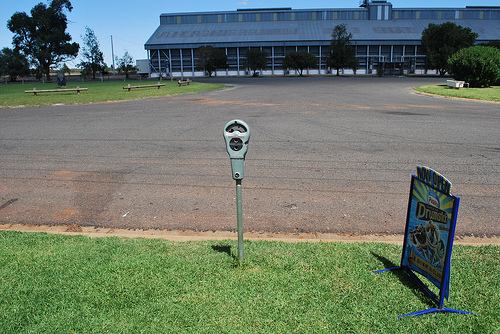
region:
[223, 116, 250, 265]
a lone parking meter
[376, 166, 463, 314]
a sign advertising icecream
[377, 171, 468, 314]
colorful sign in a blue frame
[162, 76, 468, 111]
large empty parking lot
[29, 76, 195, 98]
log railing on the grass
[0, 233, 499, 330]
grass is think and green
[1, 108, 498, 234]
a paved roadway passes the parking meter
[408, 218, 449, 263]
three ice cream cones against a blue background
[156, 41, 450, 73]
front of the building is screened in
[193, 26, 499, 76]
bushes and trees grow against the front of the building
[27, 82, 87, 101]
Small wooden bench in the grass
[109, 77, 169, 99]
Small wooden bench in the grass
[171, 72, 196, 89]
Small wooden bench in the grass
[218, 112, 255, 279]
Metal parking meter in the grass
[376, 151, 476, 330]
Colorful sign in the grass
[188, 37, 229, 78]
Large tree by a building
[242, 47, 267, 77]
Large tree by a building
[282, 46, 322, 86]
Large tree by a building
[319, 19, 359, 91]
Large tree by a building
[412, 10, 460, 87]
Large tree by a building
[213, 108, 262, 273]
the parking meter in the grass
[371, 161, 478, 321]
the sign on the grass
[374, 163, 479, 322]
the blue frame of the sign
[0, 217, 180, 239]
the curb along the road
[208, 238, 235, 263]
the shadow of the parking meter in the grass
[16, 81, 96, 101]
the wooden log on the grass in the field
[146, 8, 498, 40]
the roof of the building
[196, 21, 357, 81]
the row of trees in front of the building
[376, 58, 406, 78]
the entrance to the building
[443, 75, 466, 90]
the white bench in the grass by the bush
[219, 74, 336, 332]
a parking meter on a pole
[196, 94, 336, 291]
a parking meter on a metal pole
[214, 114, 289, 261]
a pole with a parking meter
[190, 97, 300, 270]
a metal pole with a parking meter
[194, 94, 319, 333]
a pole in the grass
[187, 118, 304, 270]
a metal pole in the grass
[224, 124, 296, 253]
a parking meter in the grass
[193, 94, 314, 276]
grass with a parking meter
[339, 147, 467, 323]
a sign on the grass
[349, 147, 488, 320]
a sign on the green grass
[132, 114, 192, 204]
this is the road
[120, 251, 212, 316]
these are the grass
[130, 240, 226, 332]
the grass are green in color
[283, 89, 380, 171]
the road is clean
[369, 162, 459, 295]
this is a poster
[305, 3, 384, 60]
this is a building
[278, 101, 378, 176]
the road is tarmacked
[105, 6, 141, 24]
this is the sky